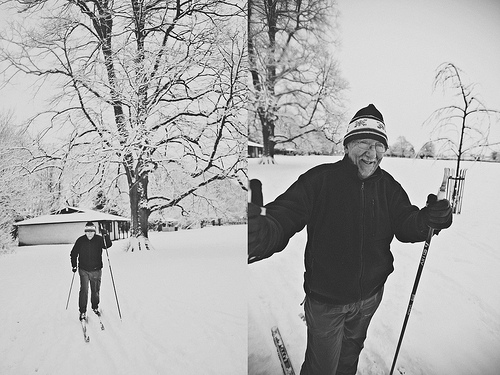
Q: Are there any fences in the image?
A: No, there are no fences.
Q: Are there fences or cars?
A: No, there are no fences or cars.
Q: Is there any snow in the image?
A: Yes, there is snow.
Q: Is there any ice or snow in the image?
A: Yes, there is snow.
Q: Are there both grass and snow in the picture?
A: No, there is snow but no grass.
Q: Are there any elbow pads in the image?
A: No, there are no elbow pads.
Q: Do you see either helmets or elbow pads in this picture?
A: No, there are no elbow pads or helmets.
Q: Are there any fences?
A: No, there are no fences.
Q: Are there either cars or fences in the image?
A: No, there are no fences or cars.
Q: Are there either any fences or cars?
A: No, there are no fences or cars.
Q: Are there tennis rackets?
A: No, there are no tennis rackets.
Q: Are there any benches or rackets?
A: No, there are no rackets or benches.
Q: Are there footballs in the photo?
A: No, there are no footballs.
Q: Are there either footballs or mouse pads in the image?
A: No, there are no footballs or mouse pads.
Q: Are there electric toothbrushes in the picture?
A: No, there are no electric toothbrushes.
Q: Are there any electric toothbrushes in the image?
A: No, there are no electric toothbrushes.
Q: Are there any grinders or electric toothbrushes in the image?
A: No, there are no electric toothbrushes or grinders.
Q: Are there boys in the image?
A: No, there are no boys.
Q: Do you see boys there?
A: No, there are no boys.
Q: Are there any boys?
A: No, there are no boys.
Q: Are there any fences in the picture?
A: No, there are no fences.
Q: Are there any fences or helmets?
A: No, there are no fences or helmets.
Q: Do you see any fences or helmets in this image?
A: No, there are no fences or helmets.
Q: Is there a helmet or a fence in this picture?
A: No, there are no fences or helmets.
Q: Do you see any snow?
A: Yes, there is snow.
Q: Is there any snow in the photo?
A: Yes, there is snow.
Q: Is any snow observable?
A: Yes, there is snow.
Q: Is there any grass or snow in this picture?
A: Yes, there is snow.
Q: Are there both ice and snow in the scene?
A: No, there is snow but no ice.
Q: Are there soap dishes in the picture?
A: No, there are no soap dishes.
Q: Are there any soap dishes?
A: No, there are no soap dishes.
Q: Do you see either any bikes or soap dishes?
A: No, there are no soap dishes or bikes.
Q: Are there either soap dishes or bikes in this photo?
A: No, there are no soap dishes or bikes.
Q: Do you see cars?
A: No, there are no cars.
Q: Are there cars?
A: No, there are no cars.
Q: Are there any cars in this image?
A: No, there are no cars.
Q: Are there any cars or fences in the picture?
A: No, there are no cars or fences.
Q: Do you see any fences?
A: No, there are no fences.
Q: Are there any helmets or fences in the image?
A: No, there are no fences or helmets.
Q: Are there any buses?
A: No, there are no buses.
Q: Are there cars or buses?
A: No, there are no buses or cars.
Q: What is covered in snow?
A: The building is covered in snow.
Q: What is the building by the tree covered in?
A: The building is covered in snow.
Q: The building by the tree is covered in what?
A: The building is covered in snow.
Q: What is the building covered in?
A: The building is covered in snow.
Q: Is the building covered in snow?
A: Yes, the building is covered in snow.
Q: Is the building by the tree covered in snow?
A: Yes, the building is covered in snow.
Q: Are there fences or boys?
A: No, there are no boys or fences.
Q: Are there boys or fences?
A: No, there are no boys or fences.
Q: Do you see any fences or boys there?
A: No, there are no boys or fences.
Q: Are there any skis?
A: Yes, there are skis.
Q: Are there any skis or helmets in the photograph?
A: Yes, there are skis.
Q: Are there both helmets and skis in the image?
A: No, there are skis but no helmets.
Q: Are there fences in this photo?
A: No, there are no fences.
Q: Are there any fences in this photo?
A: No, there are no fences.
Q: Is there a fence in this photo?
A: No, there are no fences.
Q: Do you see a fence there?
A: No, there are no fences.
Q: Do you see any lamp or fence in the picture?
A: No, there are no fences or lamps.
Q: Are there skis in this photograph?
A: Yes, there are skis.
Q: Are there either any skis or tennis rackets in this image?
A: Yes, there are skis.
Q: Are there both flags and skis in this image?
A: No, there are skis but no flags.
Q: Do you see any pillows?
A: No, there are no pillows.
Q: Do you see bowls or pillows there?
A: No, there are no pillows or bowls.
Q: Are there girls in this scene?
A: No, there are no girls.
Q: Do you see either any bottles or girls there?
A: No, there are no girls or bottles.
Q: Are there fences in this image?
A: No, there are no fences.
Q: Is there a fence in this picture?
A: No, there are no fences.